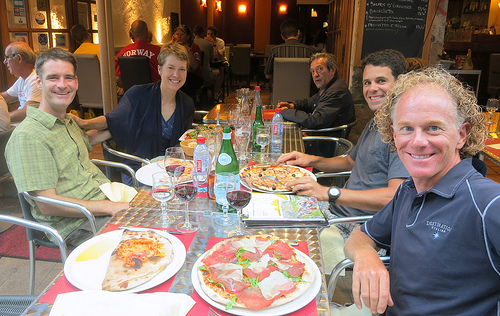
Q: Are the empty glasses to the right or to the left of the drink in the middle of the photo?
A: The glasses are to the left of the wine.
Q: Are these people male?
A: No, they are both male and female.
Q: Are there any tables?
A: Yes, there is a table.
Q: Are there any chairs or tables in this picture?
A: Yes, there is a table.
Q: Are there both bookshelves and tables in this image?
A: No, there is a table but no bookshelves.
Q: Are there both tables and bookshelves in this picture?
A: No, there is a table but no bookshelves.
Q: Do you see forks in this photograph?
A: No, there are no forks.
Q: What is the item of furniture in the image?
A: The piece of furniture is a table.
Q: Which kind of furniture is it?
A: The piece of furniture is a table.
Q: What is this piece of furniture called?
A: This is a table.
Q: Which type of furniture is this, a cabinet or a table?
A: This is a table.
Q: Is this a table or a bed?
A: This is a table.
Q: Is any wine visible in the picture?
A: Yes, there is wine.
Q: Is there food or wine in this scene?
A: Yes, there is wine.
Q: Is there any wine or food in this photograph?
A: Yes, there is wine.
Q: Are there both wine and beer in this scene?
A: No, there is wine but no beer.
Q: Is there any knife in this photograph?
A: No, there are no knives.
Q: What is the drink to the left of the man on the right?
A: The drink is wine.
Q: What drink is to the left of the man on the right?
A: The drink is wine.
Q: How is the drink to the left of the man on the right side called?
A: The drink is wine.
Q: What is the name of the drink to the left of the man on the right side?
A: The drink is wine.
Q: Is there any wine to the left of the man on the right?
A: Yes, there is wine to the left of the man.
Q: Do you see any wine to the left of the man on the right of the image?
A: Yes, there is wine to the left of the man.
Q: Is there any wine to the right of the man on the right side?
A: No, the wine is to the left of the man.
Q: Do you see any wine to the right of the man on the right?
A: No, the wine is to the left of the man.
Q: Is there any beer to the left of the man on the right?
A: No, there is wine to the left of the man.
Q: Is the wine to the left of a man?
A: Yes, the wine is to the left of a man.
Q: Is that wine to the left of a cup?
A: No, the wine is to the left of a man.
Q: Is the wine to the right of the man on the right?
A: No, the wine is to the left of the man.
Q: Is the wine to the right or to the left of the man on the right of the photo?
A: The wine is to the left of the man.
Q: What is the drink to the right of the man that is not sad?
A: The drink is wine.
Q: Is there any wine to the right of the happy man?
A: Yes, there is wine to the right of the man.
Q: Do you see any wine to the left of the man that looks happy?
A: No, the wine is to the right of the man.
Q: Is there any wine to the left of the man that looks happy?
A: No, the wine is to the right of the man.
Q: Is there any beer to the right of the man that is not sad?
A: No, there is wine to the right of the man.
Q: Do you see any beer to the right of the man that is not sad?
A: No, there is wine to the right of the man.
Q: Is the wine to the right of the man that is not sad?
A: Yes, the wine is to the right of the man.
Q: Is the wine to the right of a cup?
A: No, the wine is to the right of the man.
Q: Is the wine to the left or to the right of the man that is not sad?
A: The wine is to the right of the man.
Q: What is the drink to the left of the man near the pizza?
A: The drink is wine.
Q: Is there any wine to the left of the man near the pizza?
A: Yes, there is wine to the left of the man.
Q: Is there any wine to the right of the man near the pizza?
A: No, the wine is to the left of the man.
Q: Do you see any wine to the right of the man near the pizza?
A: No, the wine is to the left of the man.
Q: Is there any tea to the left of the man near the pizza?
A: No, there is wine to the left of the man.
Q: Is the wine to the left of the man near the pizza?
A: Yes, the wine is to the left of the man.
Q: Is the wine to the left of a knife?
A: No, the wine is to the left of the man.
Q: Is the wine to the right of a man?
A: No, the wine is to the left of a man.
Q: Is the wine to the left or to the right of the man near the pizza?
A: The wine is to the left of the man.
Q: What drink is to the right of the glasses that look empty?
A: The drink is wine.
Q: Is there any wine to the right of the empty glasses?
A: Yes, there is wine to the right of the glasses.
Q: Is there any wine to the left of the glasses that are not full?
A: No, the wine is to the right of the glasses.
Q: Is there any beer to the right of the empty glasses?
A: No, there is wine to the right of the glasses.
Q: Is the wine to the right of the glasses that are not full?
A: Yes, the wine is to the right of the glasses.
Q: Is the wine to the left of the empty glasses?
A: No, the wine is to the right of the glasses.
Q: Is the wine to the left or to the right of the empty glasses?
A: The wine is to the right of the glasses.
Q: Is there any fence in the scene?
A: No, there are no fences.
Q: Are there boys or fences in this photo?
A: No, there are no fences or boys.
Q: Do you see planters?
A: No, there are no planters.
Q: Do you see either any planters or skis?
A: No, there are no planters or skis.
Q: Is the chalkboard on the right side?
A: Yes, the chalkboard is on the right of the image.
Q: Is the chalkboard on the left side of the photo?
A: No, the chalkboard is on the right of the image.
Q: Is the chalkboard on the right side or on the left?
A: The chalkboard is on the right of the image.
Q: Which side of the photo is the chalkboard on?
A: The chalkboard is on the right of the image.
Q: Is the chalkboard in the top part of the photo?
A: Yes, the chalkboard is in the top of the image.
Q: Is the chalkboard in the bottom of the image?
A: No, the chalkboard is in the top of the image.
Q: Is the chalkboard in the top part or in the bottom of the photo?
A: The chalkboard is in the top of the image.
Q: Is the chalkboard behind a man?
A: Yes, the chalkboard is behind a man.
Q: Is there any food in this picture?
A: Yes, there is food.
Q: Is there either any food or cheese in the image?
A: Yes, there is food.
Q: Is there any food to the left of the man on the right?
A: Yes, there is food to the left of the man.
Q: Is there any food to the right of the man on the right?
A: No, the food is to the left of the man.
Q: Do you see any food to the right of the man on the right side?
A: No, the food is to the left of the man.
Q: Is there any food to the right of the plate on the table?
A: Yes, there is food to the right of the plate.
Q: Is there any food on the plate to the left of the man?
A: Yes, there is food on the plate.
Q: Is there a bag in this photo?
A: No, there are no bags.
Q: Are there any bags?
A: No, there are no bags.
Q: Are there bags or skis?
A: No, there are no bags or skis.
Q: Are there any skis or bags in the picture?
A: No, there are no bags or skis.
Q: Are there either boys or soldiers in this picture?
A: No, there are no boys or soldiers.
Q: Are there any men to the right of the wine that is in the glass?
A: Yes, there is a man to the right of the wine.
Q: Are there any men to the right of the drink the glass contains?
A: Yes, there is a man to the right of the wine.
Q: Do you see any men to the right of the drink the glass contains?
A: Yes, there is a man to the right of the wine.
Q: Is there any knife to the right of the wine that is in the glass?
A: No, there is a man to the right of the wine.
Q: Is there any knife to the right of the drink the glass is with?
A: No, there is a man to the right of the wine.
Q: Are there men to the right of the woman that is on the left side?
A: Yes, there is a man to the right of the woman.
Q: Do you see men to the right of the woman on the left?
A: Yes, there is a man to the right of the woman.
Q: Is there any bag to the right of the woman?
A: No, there is a man to the right of the woman.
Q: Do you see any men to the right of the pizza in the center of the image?
A: Yes, there is a man to the right of the pizza.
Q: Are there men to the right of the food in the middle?
A: Yes, there is a man to the right of the pizza.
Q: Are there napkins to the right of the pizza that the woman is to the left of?
A: No, there is a man to the right of the pizza.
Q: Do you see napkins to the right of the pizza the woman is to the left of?
A: No, there is a man to the right of the pizza.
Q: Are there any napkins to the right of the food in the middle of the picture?
A: No, there is a man to the right of the pizza.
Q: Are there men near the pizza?
A: Yes, there is a man near the pizza.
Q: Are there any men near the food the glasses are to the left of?
A: Yes, there is a man near the pizza.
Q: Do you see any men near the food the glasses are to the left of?
A: Yes, there is a man near the pizza.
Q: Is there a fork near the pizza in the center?
A: No, there is a man near the pizza.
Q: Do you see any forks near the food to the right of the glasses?
A: No, there is a man near the pizza.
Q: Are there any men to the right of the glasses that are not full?
A: Yes, there is a man to the right of the glasses.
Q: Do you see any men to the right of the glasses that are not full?
A: Yes, there is a man to the right of the glasses.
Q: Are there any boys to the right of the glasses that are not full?
A: No, there is a man to the right of the glasses.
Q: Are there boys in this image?
A: No, there are no boys.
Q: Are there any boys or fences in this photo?
A: No, there are no boys or fences.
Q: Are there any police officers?
A: No, there are no police officers.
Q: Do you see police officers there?
A: No, there are no police officers.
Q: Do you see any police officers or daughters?
A: No, there are no police officers or daughters.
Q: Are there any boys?
A: No, there are no boys.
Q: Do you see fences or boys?
A: No, there are no boys or fences.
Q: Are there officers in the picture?
A: No, there are no officers.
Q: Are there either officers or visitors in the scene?
A: No, there are no officers or visitors.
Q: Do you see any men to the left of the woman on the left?
A: Yes, there is a man to the left of the woman.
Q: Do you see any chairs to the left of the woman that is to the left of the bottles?
A: No, there is a man to the left of the woman.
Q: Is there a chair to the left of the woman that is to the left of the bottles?
A: No, there is a man to the left of the woman.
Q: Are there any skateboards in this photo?
A: No, there are no skateboards.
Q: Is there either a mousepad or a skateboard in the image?
A: No, there are no skateboards or mouse pads.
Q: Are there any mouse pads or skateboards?
A: No, there are no skateboards or mouse pads.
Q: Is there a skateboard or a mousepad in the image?
A: No, there are no skateboards or mouse pads.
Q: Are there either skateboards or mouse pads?
A: No, there are no skateboards or mouse pads.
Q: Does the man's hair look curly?
A: Yes, the hair is curly.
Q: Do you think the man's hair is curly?
A: Yes, the hair is curly.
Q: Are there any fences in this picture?
A: No, there are no fences.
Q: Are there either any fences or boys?
A: No, there are no fences or boys.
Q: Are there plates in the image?
A: Yes, there is a plate.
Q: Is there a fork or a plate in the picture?
A: Yes, there is a plate.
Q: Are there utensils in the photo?
A: No, there are no utensils.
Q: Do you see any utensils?
A: No, there are no utensils.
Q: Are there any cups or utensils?
A: No, there are no utensils or cups.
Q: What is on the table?
A: The plate is on the table.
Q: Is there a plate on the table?
A: Yes, there is a plate on the table.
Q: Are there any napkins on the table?
A: No, there is a plate on the table.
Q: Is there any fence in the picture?
A: No, there are no fences.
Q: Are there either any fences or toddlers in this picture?
A: No, there are no fences or toddlers.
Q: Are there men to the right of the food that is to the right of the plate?
A: Yes, there is a man to the right of the food.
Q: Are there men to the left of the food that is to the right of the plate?
A: No, the man is to the right of the food.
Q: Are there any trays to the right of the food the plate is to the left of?
A: No, there is a man to the right of the food.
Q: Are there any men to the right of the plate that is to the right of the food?
A: Yes, there is a man to the right of the plate.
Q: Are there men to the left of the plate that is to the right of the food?
A: No, the man is to the right of the plate.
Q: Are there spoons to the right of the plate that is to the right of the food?
A: No, there is a man to the right of the plate.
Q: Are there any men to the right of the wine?
A: Yes, there is a man to the right of the wine.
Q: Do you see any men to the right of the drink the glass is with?
A: Yes, there is a man to the right of the wine.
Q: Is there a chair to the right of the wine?
A: No, there is a man to the right of the wine.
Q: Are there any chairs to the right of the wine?
A: No, there is a man to the right of the wine.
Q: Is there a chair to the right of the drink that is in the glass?
A: No, there is a man to the right of the wine.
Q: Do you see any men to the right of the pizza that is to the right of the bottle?
A: Yes, there is a man to the right of the pizza.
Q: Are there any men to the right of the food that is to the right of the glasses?
A: Yes, there is a man to the right of the pizza.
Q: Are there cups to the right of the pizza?
A: No, there is a man to the right of the pizza.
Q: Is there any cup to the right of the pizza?
A: No, there is a man to the right of the pizza.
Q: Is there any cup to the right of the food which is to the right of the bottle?
A: No, there is a man to the right of the pizza.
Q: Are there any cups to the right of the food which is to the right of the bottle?
A: No, there is a man to the right of the pizza.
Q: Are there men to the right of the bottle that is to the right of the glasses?
A: Yes, there is a man to the right of the bottle.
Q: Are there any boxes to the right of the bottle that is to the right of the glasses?
A: No, there is a man to the right of the bottle.